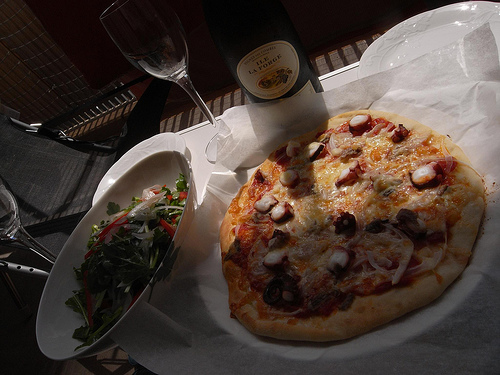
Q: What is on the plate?
A: The pizza.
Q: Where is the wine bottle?
A: Above the pizza.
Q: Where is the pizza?
A: On the table.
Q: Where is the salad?
A: In the bowl.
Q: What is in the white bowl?
A: The salad.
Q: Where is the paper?
A: Underneath the pizza.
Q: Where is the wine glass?
A: Next to the bottle.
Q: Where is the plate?
A: To the right of the pizza.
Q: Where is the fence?
A: In the distance to the left.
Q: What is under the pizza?
A: A napkin.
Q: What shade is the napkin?
A: White.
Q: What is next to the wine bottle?
A: A wine glass.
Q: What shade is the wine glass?
A: Clear.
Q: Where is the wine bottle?
A: Next to the glass.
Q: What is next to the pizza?
A: A salad.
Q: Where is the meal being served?
A: On a table.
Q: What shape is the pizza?
A: Round.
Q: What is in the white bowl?
A: The salad.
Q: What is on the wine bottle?
A: A label.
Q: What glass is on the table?
A: Wine glass.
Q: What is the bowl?
A: White.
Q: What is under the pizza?
A: Paper.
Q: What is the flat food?
A: Pizza.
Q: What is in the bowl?
A: Salad.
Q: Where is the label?
A: On the bottle.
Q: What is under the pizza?
A: Paper.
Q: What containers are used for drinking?
A: Wine glasses.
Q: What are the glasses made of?
A: Glass.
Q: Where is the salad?
A: In the bowl.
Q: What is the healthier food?
A: The salad.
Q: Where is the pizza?
A: On the paper.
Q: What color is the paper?
A: White.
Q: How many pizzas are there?
A: One.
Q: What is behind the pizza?
A: A bottle.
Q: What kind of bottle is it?
A: A wine bottle.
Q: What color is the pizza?
A: Brown, red, and yellow.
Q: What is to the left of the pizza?
A: A bowl.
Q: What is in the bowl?
A: A salad.